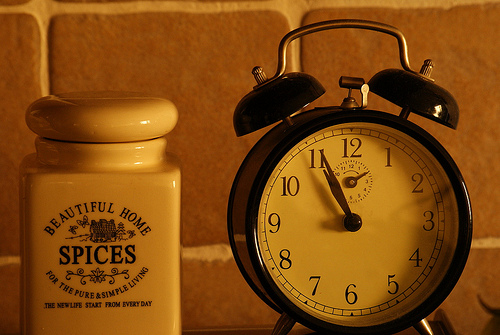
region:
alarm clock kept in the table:
[240, 50, 478, 318]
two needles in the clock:
[314, 147, 383, 232]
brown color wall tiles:
[78, 19, 214, 64]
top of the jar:
[18, 79, 189, 149]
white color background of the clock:
[297, 140, 429, 312]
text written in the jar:
[48, 195, 155, 317]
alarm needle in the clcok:
[342, 161, 373, 188]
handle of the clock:
[242, 13, 418, 95]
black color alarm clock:
[218, 80, 361, 127]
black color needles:
[318, 155, 370, 243]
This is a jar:
[18, 76, 185, 331]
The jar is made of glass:
[23, 79, 183, 331]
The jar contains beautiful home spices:
[9, 80, 196, 332]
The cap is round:
[12, 75, 188, 142]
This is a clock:
[210, 13, 490, 326]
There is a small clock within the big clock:
[333, 152, 372, 204]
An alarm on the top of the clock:
[203, 8, 475, 129]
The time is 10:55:
[225, 74, 475, 322]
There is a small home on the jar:
[71, 210, 127, 245]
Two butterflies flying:
[59, 212, 91, 240]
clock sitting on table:
[220, 19, 477, 334]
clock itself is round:
[225, 4, 487, 332]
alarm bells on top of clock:
[233, 43, 465, 140]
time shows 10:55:
[251, 114, 481, 334]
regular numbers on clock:
[251, 116, 465, 320]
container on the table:
[8, 82, 192, 334]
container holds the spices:
[20, 84, 202, 333]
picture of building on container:
[76, 212, 121, 250]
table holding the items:
[11, 309, 464, 334]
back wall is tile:
[2, 4, 499, 334]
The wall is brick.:
[4, 1, 499, 132]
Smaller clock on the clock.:
[326, 155, 379, 202]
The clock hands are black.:
[310, 143, 369, 239]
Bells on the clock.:
[226, 49, 463, 137]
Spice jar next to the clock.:
[19, 91, 194, 333]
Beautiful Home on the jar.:
[41, 194, 157, 246]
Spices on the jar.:
[53, 240, 142, 271]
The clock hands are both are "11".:
[303, 138, 372, 243]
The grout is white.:
[5, 0, 311, 48]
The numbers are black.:
[259, 130, 446, 315]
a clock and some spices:
[4, 3, 489, 327]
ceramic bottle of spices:
[15, 90, 187, 331]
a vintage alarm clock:
[221, 14, 479, 329]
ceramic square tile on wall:
[46, 6, 300, 256]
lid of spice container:
[22, 87, 182, 147]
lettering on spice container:
[34, 195, 157, 312]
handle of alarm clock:
[251, 15, 440, 87]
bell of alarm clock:
[230, 68, 330, 141]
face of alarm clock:
[251, 115, 465, 329]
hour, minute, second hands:
[310, 146, 375, 233]